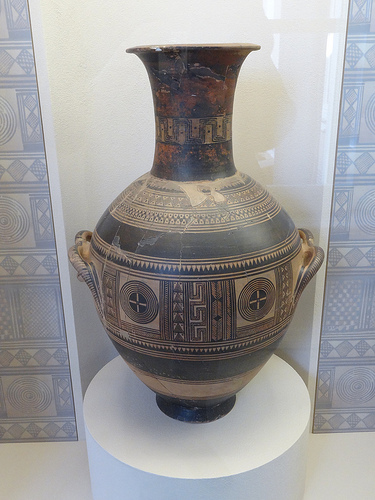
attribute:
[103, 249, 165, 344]
design — brown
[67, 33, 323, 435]
artifact — ancient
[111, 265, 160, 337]
patterns — circle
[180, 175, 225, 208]
spots — worn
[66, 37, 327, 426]
pot — old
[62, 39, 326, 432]
vase — ancient, old, big, brown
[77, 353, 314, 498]
pedestal — white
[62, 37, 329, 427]
pottery — old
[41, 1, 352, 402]
insert — shiny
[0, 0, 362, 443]
wall — blue, white, painted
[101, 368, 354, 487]
stand — white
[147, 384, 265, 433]
base — brown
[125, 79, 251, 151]
neck — brown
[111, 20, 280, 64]
rim — brown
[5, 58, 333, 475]
wall — white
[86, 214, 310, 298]
stripe — brown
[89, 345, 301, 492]
stand — white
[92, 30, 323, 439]
vase — brown, old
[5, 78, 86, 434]
pattern — geometric